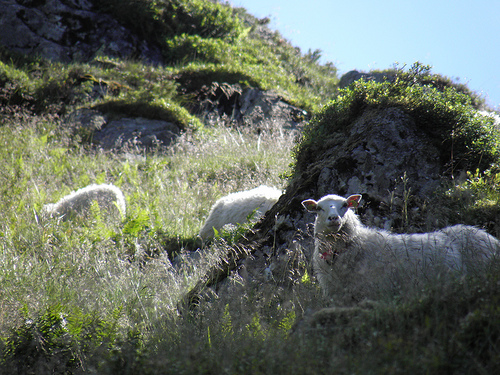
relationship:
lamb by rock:
[296, 194, 499, 316] [257, 98, 494, 272]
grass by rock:
[4, 129, 268, 333] [257, 98, 494, 272]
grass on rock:
[306, 81, 498, 173] [257, 98, 494, 272]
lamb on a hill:
[296, 194, 499, 316] [7, 5, 499, 341]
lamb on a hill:
[39, 178, 126, 238] [7, 5, 499, 341]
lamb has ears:
[296, 194, 499, 316] [301, 194, 367, 213]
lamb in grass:
[39, 178, 126, 238] [4, 129, 268, 333]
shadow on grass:
[153, 232, 204, 258] [4, 129, 268, 333]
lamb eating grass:
[39, 178, 126, 238] [4, 129, 268, 333]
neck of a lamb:
[196, 208, 218, 250] [185, 183, 281, 255]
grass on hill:
[4, 129, 268, 333] [7, 5, 499, 341]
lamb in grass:
[296, 194, 499, 316] [4, 129, 268, 333]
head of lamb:
[300, 194, 364, 243] [296, 194, 499, 316]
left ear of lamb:
[299, 197, 318, 215] [296, 194, 499, 316]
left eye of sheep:
[316, 206, 323, 214] [296, 194, 499, 316]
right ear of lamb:
[347, 192, 363, 209] [296, 194, 499, 316]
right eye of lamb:
[342, 201, 348, 209] [296, 194, 499, 316]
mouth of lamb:
[325, 222, 341, 232] [296, 194, 499, 316]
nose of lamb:
[329, 212, 340, 222] [296, 194, 499, 316]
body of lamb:
[330, 229, 498, 318] [296, 194, 499, 316]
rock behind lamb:
[257, 98, 494, 272] [296, 194, 499, 316]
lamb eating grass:
[185, 183, 281, 255] [4, 129, 268, 333]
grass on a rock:
[306, 81, 498, 173] [257, 98, 494, 272]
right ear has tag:
[347, 192, 363, 209] [351, 199, 357, 209]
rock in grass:
[257, 98, 494, 272] [4, 129, 268, 333]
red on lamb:
[318, 251, 325, 257] [296, 194, 499, 316]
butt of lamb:
[108, 182, 124, 219] [296, 194, 499, 316]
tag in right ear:
[351, 199, 357, 209] [347, 192, 363, 209]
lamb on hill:
[296, 194, 499, 316] [7, 5, 499, 341]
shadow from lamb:
[153, 232, 204, 258] [185, 183, 281, 255]